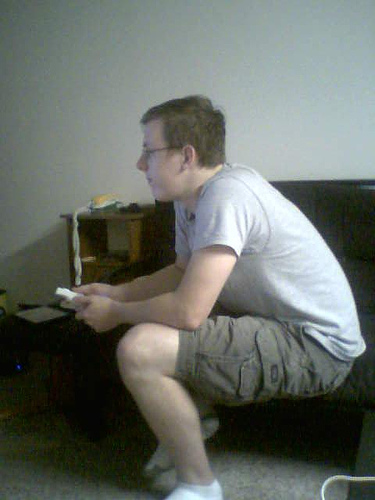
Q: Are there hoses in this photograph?
A: No, there are no hoses.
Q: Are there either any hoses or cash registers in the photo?
A: No, there are no hoses or cash registers.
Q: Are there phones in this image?
A: Yes, there is a phone.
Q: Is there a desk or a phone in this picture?
A: Yes, there is a phone.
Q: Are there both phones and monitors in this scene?
A: No, there is a phone but no monitors.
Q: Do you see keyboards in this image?
A: No, there are no keyboards.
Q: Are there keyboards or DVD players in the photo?
A: No, there are no keyboards or DVD players.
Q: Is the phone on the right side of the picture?
A: No, the phone is on the left of the image.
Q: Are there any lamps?
A: No, there are no lamps.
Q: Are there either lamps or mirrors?
A: No, there are no lamps or mirrors.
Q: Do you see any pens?
A: No, there are no pens.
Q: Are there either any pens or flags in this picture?
A: No, there are no pens or flags.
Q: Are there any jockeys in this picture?
A: No, there are no jockeys.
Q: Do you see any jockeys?
A: No, there are no jockeys.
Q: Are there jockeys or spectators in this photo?
A: No, there are no jockeys or spectators.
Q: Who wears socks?
A: The man wears socks.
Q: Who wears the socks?
A: The man wears socks.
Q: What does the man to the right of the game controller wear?
A: The man wears socks.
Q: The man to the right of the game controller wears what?
A: The man wears socks.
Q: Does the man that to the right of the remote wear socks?
A: Yes, the man wears socks.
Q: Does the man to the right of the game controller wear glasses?
A: No, the man wears socks.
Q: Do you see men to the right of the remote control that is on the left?
A: Yes, there is a man to the right of the remote control.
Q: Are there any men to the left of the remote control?
A: No, the man is to the right of the remote control.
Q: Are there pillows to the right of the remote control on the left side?
A: No, there is a man to the right of the remote control.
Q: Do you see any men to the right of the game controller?
A: Yes, there is a man to the right of the game controller.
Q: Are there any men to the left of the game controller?
A: No, the man is to the right of the game controller.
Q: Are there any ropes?
A: No, there are no ropes.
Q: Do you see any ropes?
A: No, there are no ropes.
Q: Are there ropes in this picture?
A: No, there are no ropes.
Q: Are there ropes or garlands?
A: No, there are no ropes or garlands.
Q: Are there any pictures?
A: No, there are no pictures.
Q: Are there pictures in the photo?
A: No, there are no pictures.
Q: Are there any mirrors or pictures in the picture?
A: No, there are no pictures or mirrors.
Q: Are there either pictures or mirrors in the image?
A: No, there are no pictures or mirrors.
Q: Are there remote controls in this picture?
A: Yes, there is a remote control.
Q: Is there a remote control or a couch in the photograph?
A: Yes, there is a remote control.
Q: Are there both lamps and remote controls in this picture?
A: No, there is a remote control but no lamps.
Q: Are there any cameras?
A: No, there are no cameras.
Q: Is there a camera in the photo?
A: No, there are no cameras.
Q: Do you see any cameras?
A: No, there are no cameras.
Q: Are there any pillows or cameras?
A: No, there are no cameras or pillows.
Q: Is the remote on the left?
A: Yes, the remote is on the left of the image.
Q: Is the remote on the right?
A: No, the remote is on the left of the image.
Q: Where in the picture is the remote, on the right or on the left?
A: The remote is on the left of the image.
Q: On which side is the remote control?
A: The remote control is on the left of the image.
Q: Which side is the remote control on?
A: The remote control is on the left of the image.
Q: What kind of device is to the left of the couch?
A: The device is a remote control.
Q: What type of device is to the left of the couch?
A: The device is a remote control.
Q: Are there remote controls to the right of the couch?
A: No, the remote control is to the left of the couch.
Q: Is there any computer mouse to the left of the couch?
A: No, there is a remote control to the left of the couch.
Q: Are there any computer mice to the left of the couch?
A: No, there is a remote control to the left of the couch.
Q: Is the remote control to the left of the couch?
A: Yes, the remote control is to the left of the couch.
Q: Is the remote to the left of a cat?
A: No, the remote is to the left of the couch.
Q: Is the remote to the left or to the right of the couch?
A: The remote is to the left of the couch.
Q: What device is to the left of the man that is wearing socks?
A: The device is a remote control.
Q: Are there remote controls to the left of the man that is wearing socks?
A: Yes, there is a remote control to the left of the man.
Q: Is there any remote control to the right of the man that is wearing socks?
A: No, the remote control is to the left of the man.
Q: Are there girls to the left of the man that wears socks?
A: No, there is a remote control to the left of the man.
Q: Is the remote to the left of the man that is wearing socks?
A: Yes, the remote is to the left of the man.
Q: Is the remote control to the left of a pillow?
A: No, the remote control is to the left of the man.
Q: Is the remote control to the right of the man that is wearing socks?
A: No, the remote control is to the left of the man.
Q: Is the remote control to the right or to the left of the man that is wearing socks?
A: The remote control is to the left of the man.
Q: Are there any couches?
A: Yes, there is a couch.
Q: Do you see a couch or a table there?
A: Yes, there is a couch.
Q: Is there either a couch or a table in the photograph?
A: Yes, there is a couch.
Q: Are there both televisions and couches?
A: No, there is a couch but no televisions.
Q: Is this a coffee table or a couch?
A: This is a couch.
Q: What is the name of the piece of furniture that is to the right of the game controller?
A: The piece of furniture is a couch.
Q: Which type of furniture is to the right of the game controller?
A: The piece of furniture is a couch.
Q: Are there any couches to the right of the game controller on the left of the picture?
A: Yes, there is a couch to the right of the game controller.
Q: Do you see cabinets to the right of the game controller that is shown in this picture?
A: No, there is a couch to the right of the game controller.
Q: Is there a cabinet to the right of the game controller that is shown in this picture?
A: No, there is a couch to the right of the game controller.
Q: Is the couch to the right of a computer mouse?
A: No, the couch is to the right of the game controller.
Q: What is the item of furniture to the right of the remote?
A: The piece of furniture is a couch.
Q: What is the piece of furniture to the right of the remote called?
A: The piece of furniture is a couch.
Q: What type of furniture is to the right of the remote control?
A: The piece of furniture is a couch.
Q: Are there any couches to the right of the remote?
A: Yes, there is a couch to the right of the remote.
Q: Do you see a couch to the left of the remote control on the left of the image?
A: No, the couch is to the right of the remote control.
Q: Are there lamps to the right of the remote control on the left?
A: No, there is a couch to the right of the remote control.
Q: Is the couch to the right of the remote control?
A: Yes, the couch is to the right of the remote control.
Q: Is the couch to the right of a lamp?
A: No, the couch is to the right of the remote control.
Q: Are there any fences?
A: No, there are no fences.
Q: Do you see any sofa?
A: Yes, there is a sofa.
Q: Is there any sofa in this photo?
A: Yes, there is a sofa.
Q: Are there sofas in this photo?
A: Yes, there is a sofa.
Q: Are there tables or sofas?
A: Yes, there is a sofa.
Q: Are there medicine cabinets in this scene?
A: No, there are no medicine cabinets.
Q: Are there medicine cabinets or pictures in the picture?
A: No, there are no medicine cabinets or pictures.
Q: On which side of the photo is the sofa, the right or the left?
A: The sofa is on the right of the image.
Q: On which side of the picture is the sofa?
A: The sofa is on the right of the image.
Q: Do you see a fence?
A: No, there are no fences.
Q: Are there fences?
A: No, there are no fences.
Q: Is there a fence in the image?
A: No, there are no fences.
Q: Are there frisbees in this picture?
A: No, there are no frisbees.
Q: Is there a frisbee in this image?
A: No, there are no frisbees.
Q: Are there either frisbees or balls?
A: No, there are no frisbees or balls.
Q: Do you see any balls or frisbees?
A: No, there are no frisbees or balls.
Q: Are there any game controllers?
A: Yes, there is a game controller.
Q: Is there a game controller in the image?
A: Yes, there is a game controller.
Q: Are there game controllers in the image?
A: Yes, there is a game controller.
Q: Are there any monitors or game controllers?
A: Yes, there is a game controller.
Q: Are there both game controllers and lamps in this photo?
A: No, there is a game controller but no lamps.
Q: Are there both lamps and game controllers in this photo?
A: No, there is a game controller but no lamps.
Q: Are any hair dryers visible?
A: No, there are no hair dryers.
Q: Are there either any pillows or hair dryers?
A: No, there are no hair dryers or pillows.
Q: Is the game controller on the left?
A: Yes, the game controller is on the left of the image.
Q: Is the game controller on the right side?
A: No, the game controller is on the left of the image.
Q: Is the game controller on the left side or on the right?
A: The game controller is on the left of the image.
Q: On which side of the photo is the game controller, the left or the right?
A: The game controller is on the left of the image.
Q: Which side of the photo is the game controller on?
A: The game controller is on the left of the image.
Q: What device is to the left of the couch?
A: The device is a game controller.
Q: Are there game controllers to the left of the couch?
A: Yes, there is a game controller to the left of the couch.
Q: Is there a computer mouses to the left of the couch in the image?
A: No, there is a game controller to the left of the couch.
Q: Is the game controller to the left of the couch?
A: Yes, the game controller is to the left of the couch.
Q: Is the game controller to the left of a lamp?
A: No, the game controller is to the left of the couch.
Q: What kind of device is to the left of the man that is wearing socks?
A: The device is a game controller.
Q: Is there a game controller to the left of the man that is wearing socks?
A: Yes, there is a game controller to the left of the man.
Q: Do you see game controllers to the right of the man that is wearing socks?
A: No, the game controller is to the left of the man.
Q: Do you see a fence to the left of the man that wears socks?
A: No, there is a game controller to the left of the man.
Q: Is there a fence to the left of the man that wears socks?
A: No, there is a game controller to the left of the man.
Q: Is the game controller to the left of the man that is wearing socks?
A: Yes, the game controller is to the left of the man.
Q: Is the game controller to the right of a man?
A: No, the game controller is to the left of a man.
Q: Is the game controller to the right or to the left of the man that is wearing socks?
A: The game controller is to the left of the man.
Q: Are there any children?
A: No, there are no children.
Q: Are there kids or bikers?
A: No, there are no kids or bikers.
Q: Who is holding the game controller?
A: The man is holding the game controller.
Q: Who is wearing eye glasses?
A: The man is wearing eye glasses.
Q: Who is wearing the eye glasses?
A: The man is wearing eye glasses.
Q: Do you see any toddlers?
A: No, there are no toddlers.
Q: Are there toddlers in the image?
A: No, there are no toddlers.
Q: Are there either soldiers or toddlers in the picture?
A: No, there are no toddlers or soldiers.